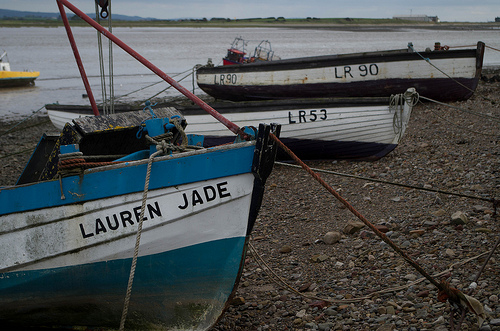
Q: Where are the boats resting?
A: Beach.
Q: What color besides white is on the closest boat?
A: Blue.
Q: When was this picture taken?
A: Evening.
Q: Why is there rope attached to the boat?
A: Tie down boat.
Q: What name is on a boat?
A: Lauren jade.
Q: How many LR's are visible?
A: Three.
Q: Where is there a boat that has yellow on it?
A: In water on left.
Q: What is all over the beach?
A: Rocks.